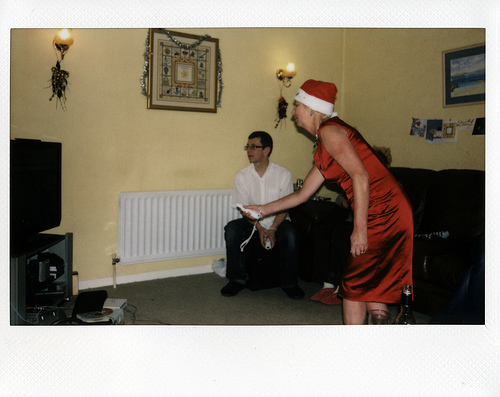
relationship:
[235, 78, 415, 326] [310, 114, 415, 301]
woman wearing shirt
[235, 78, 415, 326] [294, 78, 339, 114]
woman has hat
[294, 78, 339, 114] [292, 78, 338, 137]
hat on head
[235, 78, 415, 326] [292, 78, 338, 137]
woman has head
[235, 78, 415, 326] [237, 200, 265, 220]
woman has hand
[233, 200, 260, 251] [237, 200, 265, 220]
remote in hand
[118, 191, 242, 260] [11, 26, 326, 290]
radiator against wall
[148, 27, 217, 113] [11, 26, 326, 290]
picture on wall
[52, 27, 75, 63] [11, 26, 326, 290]
lamp on wall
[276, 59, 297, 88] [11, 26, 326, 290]
lamp on wall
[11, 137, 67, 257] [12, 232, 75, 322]
tv on stand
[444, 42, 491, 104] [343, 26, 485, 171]
picture on wall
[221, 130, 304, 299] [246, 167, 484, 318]
man sitting on couch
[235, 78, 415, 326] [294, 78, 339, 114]
woman wearing hat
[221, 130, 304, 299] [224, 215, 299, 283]
man wearing jeans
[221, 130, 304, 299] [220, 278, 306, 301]
man wearing shoes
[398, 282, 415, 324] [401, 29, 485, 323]
bottle in background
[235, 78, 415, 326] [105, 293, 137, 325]
woman playing wii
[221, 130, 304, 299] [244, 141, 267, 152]
man wearing glasses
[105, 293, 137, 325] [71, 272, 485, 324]
wii on floor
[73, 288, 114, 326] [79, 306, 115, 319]
case has discs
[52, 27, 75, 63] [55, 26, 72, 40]
lamp has light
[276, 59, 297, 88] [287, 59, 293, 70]
lamp has light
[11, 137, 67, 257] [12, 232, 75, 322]
flat screen tv on stand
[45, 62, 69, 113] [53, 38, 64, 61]
quilt on string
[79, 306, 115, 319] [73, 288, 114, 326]
discs are in case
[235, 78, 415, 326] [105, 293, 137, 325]
woman plays wii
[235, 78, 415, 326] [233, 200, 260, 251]
woman holding remote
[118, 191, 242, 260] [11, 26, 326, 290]
radiator attached to wall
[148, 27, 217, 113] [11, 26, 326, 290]
picture hangs on wall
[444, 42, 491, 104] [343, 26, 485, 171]
picture hangs on wall